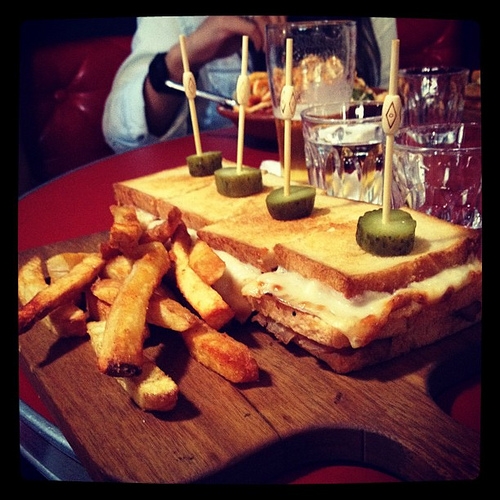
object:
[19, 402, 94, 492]
table edge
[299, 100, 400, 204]
cups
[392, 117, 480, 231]
empty glass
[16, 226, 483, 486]
board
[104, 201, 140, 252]
fry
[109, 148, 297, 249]
sandwich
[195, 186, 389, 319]
sandwich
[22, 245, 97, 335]
fries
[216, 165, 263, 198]
pickle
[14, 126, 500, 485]
table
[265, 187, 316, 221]
pickle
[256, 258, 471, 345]
cheese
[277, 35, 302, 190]
stick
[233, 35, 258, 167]
stick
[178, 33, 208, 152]
stick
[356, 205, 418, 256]
pickle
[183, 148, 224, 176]
pickle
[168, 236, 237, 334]
fries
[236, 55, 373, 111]
food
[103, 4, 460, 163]
lady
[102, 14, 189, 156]
arm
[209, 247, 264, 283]
cheese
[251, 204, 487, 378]
sandwich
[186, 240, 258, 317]
fries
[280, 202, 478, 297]
bread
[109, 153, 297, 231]
bread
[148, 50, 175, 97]
item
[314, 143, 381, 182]
water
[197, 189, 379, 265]
bread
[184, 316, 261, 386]
fries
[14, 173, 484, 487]
platter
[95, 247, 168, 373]
fries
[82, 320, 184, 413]
fries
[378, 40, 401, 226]
skewer